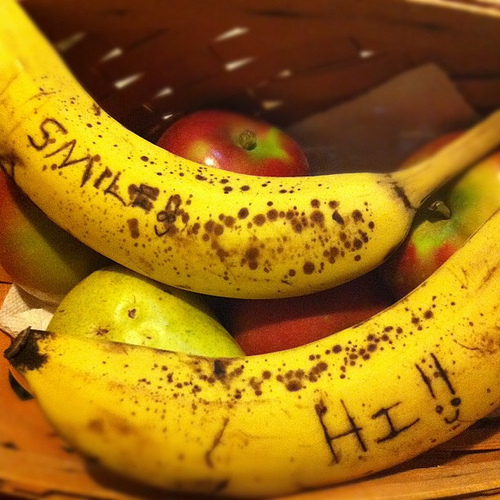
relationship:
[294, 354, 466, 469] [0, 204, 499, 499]
carving on a banana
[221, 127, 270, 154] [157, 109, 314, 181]
stem on a apple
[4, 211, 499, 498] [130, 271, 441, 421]
banana has dot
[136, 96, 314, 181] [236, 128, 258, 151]
apple has a stem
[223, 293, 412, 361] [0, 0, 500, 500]
apple in a basket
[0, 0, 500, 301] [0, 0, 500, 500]
banana in a basket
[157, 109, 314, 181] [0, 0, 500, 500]
apple in a basket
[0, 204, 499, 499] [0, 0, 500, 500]
banana in a basket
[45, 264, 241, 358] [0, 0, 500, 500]
fruit in a basket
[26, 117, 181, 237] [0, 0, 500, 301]
drawing on a banana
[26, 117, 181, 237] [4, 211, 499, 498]
drawing on a banana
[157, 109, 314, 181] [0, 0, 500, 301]
apple behind banana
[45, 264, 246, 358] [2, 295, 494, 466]
fruit behind banana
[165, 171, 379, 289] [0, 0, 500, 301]
dot on banana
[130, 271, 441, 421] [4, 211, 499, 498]
dot on banana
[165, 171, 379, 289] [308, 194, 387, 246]
dot on banana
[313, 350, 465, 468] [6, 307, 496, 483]
carving on banana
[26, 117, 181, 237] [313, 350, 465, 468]
drawing on carving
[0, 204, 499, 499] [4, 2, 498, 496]
banana inside basket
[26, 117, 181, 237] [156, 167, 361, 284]
drawing on banana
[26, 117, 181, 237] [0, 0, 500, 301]
drawing on banana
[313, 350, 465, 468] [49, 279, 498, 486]
carving on banana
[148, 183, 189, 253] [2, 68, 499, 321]
drawing on banana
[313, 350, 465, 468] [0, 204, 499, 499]
carving written on banana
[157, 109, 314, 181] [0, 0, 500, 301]
apple next to banana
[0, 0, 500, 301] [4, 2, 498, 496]
banana in basket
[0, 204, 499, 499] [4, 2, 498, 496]
banana in basket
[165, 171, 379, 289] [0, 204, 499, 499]
dot on banana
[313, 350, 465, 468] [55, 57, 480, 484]
carving on banana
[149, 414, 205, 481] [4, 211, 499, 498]
dots on banana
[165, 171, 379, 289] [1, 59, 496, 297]
dot on banana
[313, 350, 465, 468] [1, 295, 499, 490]
carving on banana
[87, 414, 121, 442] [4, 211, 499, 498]
dots on banana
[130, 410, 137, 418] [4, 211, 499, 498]
dot on banana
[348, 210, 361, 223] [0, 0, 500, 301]
dot on banana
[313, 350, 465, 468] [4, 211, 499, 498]
carving on banana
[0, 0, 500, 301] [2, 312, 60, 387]
banana has banana top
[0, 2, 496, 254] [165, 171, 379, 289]
banana has dot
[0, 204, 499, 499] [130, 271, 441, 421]
banana has dot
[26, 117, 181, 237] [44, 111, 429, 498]
drawing on banana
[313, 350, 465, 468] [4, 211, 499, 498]
carving written on banana